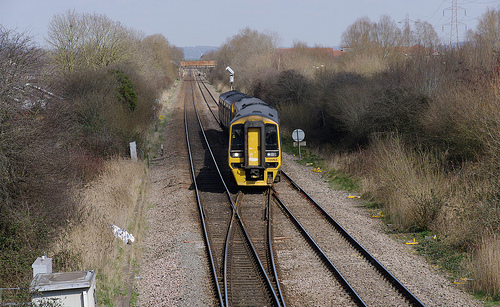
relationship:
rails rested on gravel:
[180, 69, 423, 307] [144, 172, 457, 304]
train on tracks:
[209, 82, 291, 199] [195, 187, 417, 305]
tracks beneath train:
[195, 172, 296, 197] [209, 82, 291, 199]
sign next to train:
[289, 126, 310, 162] [209, 82, 291, 199]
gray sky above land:
[1, 4, 481, 44] [12, 43, 499, 303]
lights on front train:
[228, 147, 279, 160] [209, 82, 291, 199]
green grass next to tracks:
[288, 142, 352, 193] [195, 187, 417, 305]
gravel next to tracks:
[148, 163, 191, 301] [195, 187, 417, 305]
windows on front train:
[228, 119, 280, 151] [209, 82, 291, 199]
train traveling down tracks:
[209, 82, 291, 199] [195, 187, 417, 305]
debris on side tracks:
[314, 166, 440, 250] [195, 187, 417, 305]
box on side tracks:
[28, 253, 100, 306] [195, 187, 417, 305]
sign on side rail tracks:
[289, 126, 310, 162] [191, 126, 406, 307]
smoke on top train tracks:
[197, 178, 318, 227] [197, 188, 331, 239]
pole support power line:
[443, 3, 466, 45] [406, 2, 453, 35]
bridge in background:
[176, 57, 217, 70] [134, 37, 319, 73]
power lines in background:
[408, 1, 487, 44] [4, 17, 496, 58]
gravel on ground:
[148, 163, 191, 301] [180, 69, 423, 307]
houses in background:
[257, 39, 457, 64] [4, 17, 496, 58]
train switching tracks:
[209, 82, 291, 199] [195, 187, 417, 305]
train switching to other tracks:
[209, 82, 291, 199] [195, 187, 417, 305]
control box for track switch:
[28, 253, 100, 306] [195, 187, 417, 305]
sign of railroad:
[289, 126, 310, 162] [180, 69, 423, 307]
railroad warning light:
[175, 66, 370, 306] [221, 61, 242, 91]